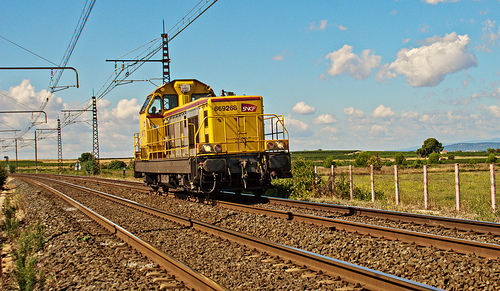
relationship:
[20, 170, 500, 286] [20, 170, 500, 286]
rail on rail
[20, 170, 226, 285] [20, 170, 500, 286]
rail on rail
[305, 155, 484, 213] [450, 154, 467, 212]
fence has post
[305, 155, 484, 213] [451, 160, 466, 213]
fence has post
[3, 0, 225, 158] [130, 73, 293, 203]
cables above train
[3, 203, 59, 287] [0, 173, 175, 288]
weeds growing in gravel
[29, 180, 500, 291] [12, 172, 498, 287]
brown rocks on tracks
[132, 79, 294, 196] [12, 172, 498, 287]
headlights sitting on tracks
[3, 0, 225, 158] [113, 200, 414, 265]
cables going up tracks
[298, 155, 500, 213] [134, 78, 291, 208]
fence on right side of train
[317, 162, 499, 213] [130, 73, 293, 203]
meadow to right of train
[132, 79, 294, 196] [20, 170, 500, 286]
headlights on rail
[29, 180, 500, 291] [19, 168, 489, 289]
brown rocks on ground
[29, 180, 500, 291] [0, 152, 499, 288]
brown rocks on ground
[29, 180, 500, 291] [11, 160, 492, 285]
brown rocks on ground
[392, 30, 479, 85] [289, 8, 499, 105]
clouds in sky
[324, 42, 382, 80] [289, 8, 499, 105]
clouds in sky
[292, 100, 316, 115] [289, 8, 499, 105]
clouds in sky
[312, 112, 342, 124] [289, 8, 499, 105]
clouds in sky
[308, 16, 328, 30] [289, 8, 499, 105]
clouds in sky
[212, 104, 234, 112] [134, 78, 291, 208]
numbers on train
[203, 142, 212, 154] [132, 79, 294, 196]
headlights on headlights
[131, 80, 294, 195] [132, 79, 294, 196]
headlights on headlights